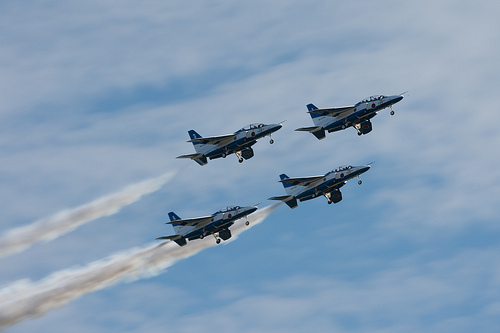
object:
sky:
[5, 4, 500, 91]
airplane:
[176, 120, 286, 167]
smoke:
[0, 242, 171, 333]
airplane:
[265, 161, 377, 211]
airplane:
[153, 203, 264, 251]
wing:
[187, 132, 234, 147]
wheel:
[232, 154, 249, 165]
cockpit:
[238, 121, 265, 133]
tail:
[188, 129, 208, 152]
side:
[194, 138, 242, 158]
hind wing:
[174, 150, 198, 161]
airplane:
[291, 91, 403, 143]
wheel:
[268, 133, 276, 146]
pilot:
[226, 204, 237, 215]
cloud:
[1, 4, 497, 89]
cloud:
[378, 122, 499, 332]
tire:
[268, 138, 275, 146]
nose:
[266, 123, 283, 136]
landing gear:
[240, 146, 257, 161]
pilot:
[252, 122, 259, 127]